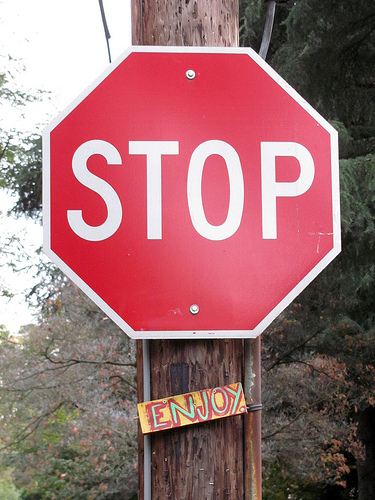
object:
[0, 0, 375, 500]
trees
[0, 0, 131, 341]
sky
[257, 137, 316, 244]
letter p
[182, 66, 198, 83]
top screw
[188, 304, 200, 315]
bottom screw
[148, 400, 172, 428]
letter e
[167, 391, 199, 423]
letter n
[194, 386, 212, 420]
letter j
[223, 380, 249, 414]
letter y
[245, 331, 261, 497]
pipe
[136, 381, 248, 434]
enjoy sign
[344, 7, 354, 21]
leaves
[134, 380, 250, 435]
sign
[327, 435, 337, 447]
leaves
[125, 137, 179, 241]
t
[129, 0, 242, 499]
telephone pole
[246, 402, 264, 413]
clips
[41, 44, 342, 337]
sign